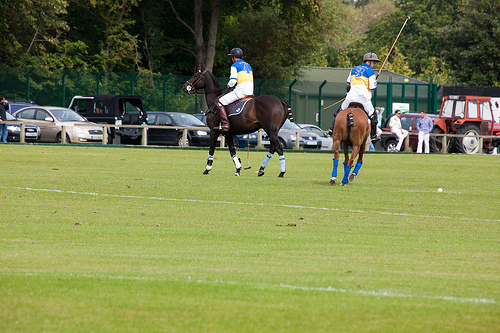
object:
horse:
[181, 63, 289, 178]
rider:
[212, 48, 256, 132]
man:
[326, 52, 383, 144]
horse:
[329, 102, 371, 187]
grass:
[42, 200, 67, 231]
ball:
[436, 187, 445, 193]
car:
[11, 106, 109, 144]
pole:
[377, 14, 412, 75]